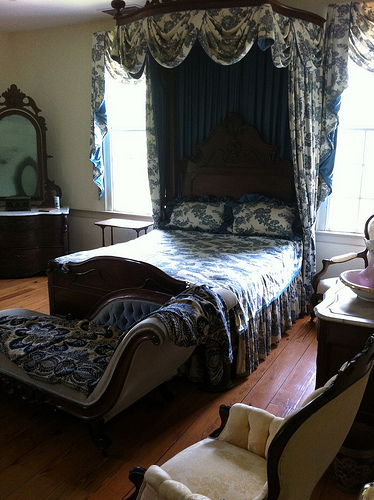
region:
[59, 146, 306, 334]
a bed in a bedroom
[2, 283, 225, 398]
chaise at the foot of the bed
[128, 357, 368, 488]
chair in the bedroom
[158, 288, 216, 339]
blanket on the chaise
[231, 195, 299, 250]
pillow on the bed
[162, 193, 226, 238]
pillow on the bed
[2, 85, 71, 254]
dresser in the bedroom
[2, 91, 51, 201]
mirror on the dresser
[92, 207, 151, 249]
table next to the bed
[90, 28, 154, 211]
window next to the bed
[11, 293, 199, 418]
chaise at the bottom of the bed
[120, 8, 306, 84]
fabric above the headboard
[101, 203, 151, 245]
side table next to the bed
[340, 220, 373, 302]
basin on the table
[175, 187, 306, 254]
two pillows on the bed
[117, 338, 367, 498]
white antique chair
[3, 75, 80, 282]
vanity in the corner of room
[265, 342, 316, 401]
dark wood on the floor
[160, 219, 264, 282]
fabric on the bed is blue and white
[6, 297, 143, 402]
blanket on the chaise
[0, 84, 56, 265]
dressing table in the bedroom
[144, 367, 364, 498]
wooden cushion chair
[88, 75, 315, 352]
wooden cot with matress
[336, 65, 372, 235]
window in the bedroom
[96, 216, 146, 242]
side table of the bed room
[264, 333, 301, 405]
browncolor wooden floor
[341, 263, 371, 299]
bowl kept in the side table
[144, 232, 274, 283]
white color designed bedspread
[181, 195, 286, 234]
two pillow kept in the matress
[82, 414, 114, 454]
stand of the wooden chair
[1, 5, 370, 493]
large bedroom space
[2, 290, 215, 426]
furniture at the foot of the bed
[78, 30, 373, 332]
large bed in center of windows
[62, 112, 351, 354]
large bed next to window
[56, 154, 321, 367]
large bed between two windows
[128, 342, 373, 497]
white old style chair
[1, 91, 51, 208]
large mirror near wall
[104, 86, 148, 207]
sunlight coming from window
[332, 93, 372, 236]
sunlight coming from window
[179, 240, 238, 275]
green pattern on bed cover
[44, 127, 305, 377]
Bed with blue and white cover.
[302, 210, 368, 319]
White and wood chair near window.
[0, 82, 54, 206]
Old black dresser mirror.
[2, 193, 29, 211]
Wood box on dresser.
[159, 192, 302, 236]
Two blue and white pillows.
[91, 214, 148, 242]
Wood table beside bed.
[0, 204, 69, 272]
Dark dresser with white counter.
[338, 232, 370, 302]
White pitcher in basin bowl.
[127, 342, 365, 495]
White and wood chair upholstered armrests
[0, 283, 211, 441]
Grey and wood fainting couch.